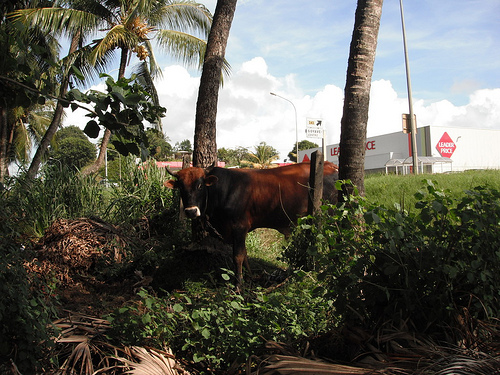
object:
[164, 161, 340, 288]
cow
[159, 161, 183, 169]
building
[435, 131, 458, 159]
sign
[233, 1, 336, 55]
sky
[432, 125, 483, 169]
building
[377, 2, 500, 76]
sky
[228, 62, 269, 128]
clouds